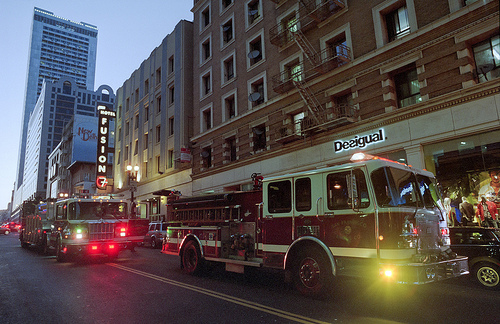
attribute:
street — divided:
[0, 230, 396, 324]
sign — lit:
[334, 129, 388, 153]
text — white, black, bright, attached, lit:
[93, 103, 117, 191]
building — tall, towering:
[13, 2, 99, 222]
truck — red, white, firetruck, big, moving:
[166, 159, 466, 288]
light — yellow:
[375, 259, 401, 283]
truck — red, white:
[23, 194, 129, 257]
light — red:
[91, 241, 116, 254]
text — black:
[325, 131, 401, 146]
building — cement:
[193, 0, 500, 262]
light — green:
[73, 227, 84, 235]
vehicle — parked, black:
[444, 223, 497, 287]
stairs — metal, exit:
[272, 0, 362, 137]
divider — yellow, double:
[96, 261, 310, 318]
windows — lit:
[192, 0, 497, 175]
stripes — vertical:
[115, 14, 190, 182]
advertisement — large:
[72, 113, 116, 160]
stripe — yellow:
[106, 261, 325, 321]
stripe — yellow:
[112, 252, 327, 320]